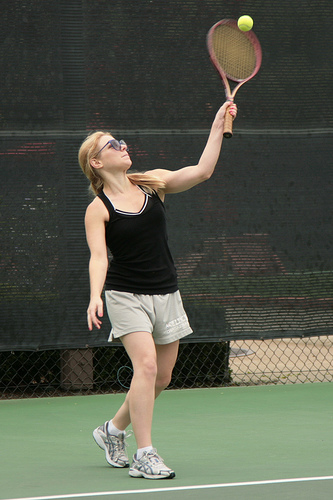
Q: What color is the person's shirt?
A: Black.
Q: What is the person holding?
A: A tennis racket.